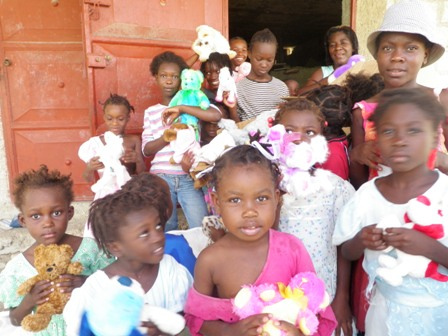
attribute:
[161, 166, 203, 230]
pants — blue, jean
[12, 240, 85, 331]
bear — teddy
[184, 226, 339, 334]
t shirt — pink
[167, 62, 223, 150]
bear — blue-green, teddy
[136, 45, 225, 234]
child — young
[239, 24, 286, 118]
child — young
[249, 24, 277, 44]
hair — short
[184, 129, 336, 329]
child — young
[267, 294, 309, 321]
bear — blue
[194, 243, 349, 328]
bear — stuffed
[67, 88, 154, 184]
child — young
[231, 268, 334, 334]
teddy bear — pink, white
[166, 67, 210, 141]
teddy bear — blue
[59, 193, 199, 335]
child — young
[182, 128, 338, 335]
girl — young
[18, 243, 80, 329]
bear — brown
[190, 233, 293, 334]
top — pink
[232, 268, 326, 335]
animal — pink, stuffed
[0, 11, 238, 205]
door — large, red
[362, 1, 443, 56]
hat — white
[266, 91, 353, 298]
girl — little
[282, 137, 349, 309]
teddy bear — white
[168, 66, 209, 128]
bear — blue-green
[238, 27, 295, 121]
child — young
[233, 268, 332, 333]
bear — teddy